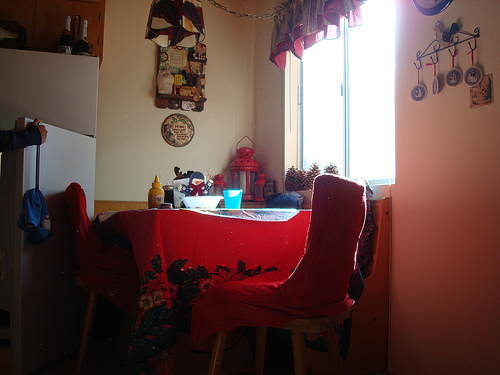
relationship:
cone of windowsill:
[323, 165, 339, 175] [287, 149, 392, 210]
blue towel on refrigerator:
[22, 183, 49, 244] [39, 51, 99, 222]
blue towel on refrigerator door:
[22, 183, 49, 244] [40, 125, 95, 192]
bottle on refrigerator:
[57, 13, 73, 56] [2, 52, 99, 372]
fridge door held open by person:
[17, 114, 117, 364] [17, 117, 44, 145]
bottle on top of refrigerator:
[57, 13, 73, 56] [6, 46, 100, 368]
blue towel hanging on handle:
[16, 188, 51, 244] [21, 110, 55, 138]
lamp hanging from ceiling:
[146, 5, 201, 48] [142, 1, 311, 30]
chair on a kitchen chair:
[191, 174, 370, 375] [175, 168, 364, 373]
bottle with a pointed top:
[147, 173, 166, 208] [153, 173, 159, 187]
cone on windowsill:
[323, 165, 339, 175] [275, 157, 398, 222]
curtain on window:
[254, 2, 379, 73] [237, 1, 419, 208]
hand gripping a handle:
[28, 116, 51, 145] [35, 122, 42, 202]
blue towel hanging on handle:
[16, 188, 51, 244] [35, 143, 41, 193]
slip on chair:
[162, 170, 371, 335] [190, 170, 353, 364]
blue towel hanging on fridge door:
[16, 188, 51, 244] [12, 114, 117, 372]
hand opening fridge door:
[28, 116, 51, 145] [12, 114, 117, 372]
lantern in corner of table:
[229, 134, 265, 203] [96, 205, 363, 375]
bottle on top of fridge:
[62, 13, 74, 53] [0, 47, 82, 345]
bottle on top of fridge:
[75, 18, 92, 55] [0, 47, 82, 345]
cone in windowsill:
[284, 165, 296, 188] [282, 177, 394, 194]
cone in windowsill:
[295, 169, 305, 188] [282, 177, 394, 194]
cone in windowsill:
[304, 161, 318, 188] [282, 177, 394, 194]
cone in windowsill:
[325, 163, 338, 173] [282, 177, 394, 194]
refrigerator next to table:
[2, 107, 112, 278] [92, 205, 310, 366]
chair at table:
[256, 121, 409, 332] [113, 133, 298, 257]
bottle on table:
[147, 173, 164, 208] [92, 205, 310, 366]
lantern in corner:
[224, 126, 263, 206] [231, 2, 285, 199]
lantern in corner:
[209, 172, 226, 197] [217, 0, 283, 204]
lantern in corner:
[229, 134, 265, 203] [217, 0, 283, 204]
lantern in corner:
[251, 171, 267, 202] [217, 0, 283, 204]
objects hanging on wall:
[408, 17, 488, 104] [386, 4, 498, 369]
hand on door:
[20, 112, 54, 156] [12, 99, 108, 371]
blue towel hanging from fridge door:
[16, 188, 51, 244] [12, 114, 117, 372]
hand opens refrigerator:
[28, 116, 51, 145] [2, 52, 99, 372]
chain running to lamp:
[190, 0, 289, 21] [146, 5, 201, 48]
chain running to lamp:
[198, 0, 290, 22] [146, 5, 201, 48]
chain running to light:
[190, 0, 289, 21] [145, 0, 208, 48]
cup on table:
[221, 187, 246, 214] [96, 197, 361, 310]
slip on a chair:
[188, 169, 368, 346] [187, 175, 376, 372]